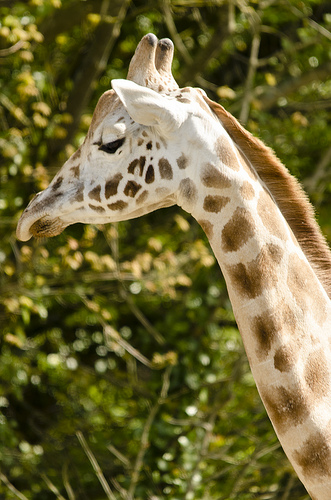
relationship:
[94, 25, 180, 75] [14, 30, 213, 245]
horns on head/neck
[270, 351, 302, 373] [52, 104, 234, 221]
spot on giraffe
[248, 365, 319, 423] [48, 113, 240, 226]
spot on giraffe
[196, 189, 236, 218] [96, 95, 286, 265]
spot on giraffe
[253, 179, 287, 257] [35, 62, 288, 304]
spot on giraffe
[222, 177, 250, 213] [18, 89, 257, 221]
spot on giraffe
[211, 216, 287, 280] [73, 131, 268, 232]
spot on giraffe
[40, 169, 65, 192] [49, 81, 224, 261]
spot on giraffe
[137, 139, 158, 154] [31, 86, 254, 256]
spot on giraffe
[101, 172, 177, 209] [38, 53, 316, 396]
dots of giraffe